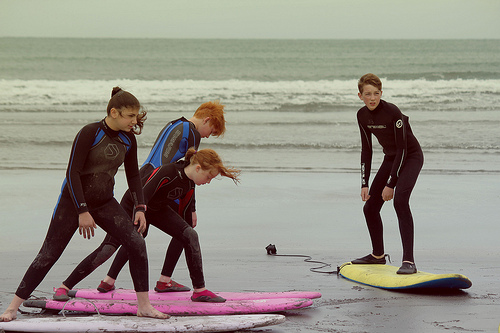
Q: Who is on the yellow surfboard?
A: The boy.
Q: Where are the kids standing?
A: On surfboards.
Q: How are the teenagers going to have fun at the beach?
A: Surfboarding.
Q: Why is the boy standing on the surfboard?
A: Practicing surfboarding.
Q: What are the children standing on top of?
A: Surfboards.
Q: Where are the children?
A: Beach.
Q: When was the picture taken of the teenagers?
A: Morning.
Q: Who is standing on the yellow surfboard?
A: Boy in black wetsuit.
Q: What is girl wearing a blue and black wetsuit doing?
A: Posing on a white surfboard.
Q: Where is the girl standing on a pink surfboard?
A: Between a boy and another girl.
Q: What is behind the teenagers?
A: Water on the beach.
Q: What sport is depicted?
A: Surfing.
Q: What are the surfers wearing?
A: Wet suits.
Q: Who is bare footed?
A: The women standing on the white surfboard.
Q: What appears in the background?
A: Water.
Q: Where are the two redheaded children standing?
A: On the pink surfboards.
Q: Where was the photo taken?
A: On the beach.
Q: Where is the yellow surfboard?
A: On the righthand side of the photo.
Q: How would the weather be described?
A: Windy and overcast.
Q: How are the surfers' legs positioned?
A: One leg is in front of the other.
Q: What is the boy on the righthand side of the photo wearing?
A: A black wet suit.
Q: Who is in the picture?
A: Surfers.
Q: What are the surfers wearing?
A: Wet suits.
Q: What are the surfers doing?
A: Practicing.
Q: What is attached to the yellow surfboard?
A: A cable.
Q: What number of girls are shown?
A: Two.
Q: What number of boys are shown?
A: Two.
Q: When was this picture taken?
A: The daytime.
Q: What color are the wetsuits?
A: Black.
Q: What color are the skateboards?
A: Yellow, pink and white.